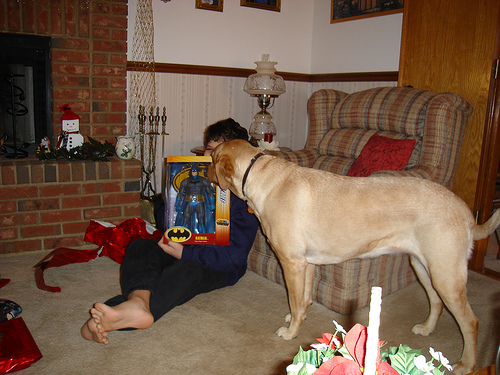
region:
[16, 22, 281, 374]
A boy opening presents.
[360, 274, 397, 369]
White handle to flower container.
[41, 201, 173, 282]
Red wrapping paper.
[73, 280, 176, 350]
There are no socks on feet.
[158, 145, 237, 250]
A box with Batman.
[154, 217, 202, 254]
A black and yellow batman logo.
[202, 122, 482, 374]
A large beige dog.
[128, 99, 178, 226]
Set of fireplace tools.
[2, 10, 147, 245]
A red brick fireplace.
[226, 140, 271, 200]
Collar on dog's neck.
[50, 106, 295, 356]
The boy sits on the floor.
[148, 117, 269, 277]
The boy holds a toy.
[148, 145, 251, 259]
The toy is a Batman doll.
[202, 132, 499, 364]
The dog is smelling the toy.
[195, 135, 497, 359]
The dog is tan.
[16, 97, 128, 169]
Christmas ornaments are on the fireplace.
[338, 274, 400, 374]
A candle is visible.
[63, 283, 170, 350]
The boy is barefoot.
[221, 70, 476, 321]
A chair is behind the boy.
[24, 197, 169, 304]
Wrapping paper is on the floor.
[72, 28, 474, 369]
child and dog in corner of living room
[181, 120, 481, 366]
tan dog looking at toy in box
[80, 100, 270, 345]
child sitting on floor showing unwrapped gift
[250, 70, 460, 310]
hefty plaid chair in rust and browns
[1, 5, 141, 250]
bricks surrounding unlit fireplace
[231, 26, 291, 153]
old-fashioned lamp with dome shapes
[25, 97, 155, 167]
vase, branch and snowman decoration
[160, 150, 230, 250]
muscular superhero standing with cape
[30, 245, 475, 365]
tan carpeting covering floor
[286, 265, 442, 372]
seasonal plastic floral basket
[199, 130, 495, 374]
Dog is tan with collar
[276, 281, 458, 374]
White basket with flowers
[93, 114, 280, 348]
Boy holding batman doll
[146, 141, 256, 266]
Batman doll in a box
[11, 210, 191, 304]
Red wrapping paper on floor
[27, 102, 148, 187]
Snowman on fireplace with red hat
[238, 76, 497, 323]
Brown striped chair with red pillow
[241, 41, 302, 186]
old lamp next to chair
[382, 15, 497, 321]
Wooden door behind chair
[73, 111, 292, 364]
Boy not wearing shoes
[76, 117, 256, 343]
A boy holding a batman action figure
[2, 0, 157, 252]
The fireplace is made of brick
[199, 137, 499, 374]
The tan dog is sniffing the box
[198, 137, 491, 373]
The black collar on the tan dog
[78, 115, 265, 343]
The boy is sitting on the floor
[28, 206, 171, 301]
The gift wrapping is on the floor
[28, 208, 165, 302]
The gift wrapping is red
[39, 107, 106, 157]
The snowman at the fireplace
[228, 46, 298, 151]
The lamp behind the boy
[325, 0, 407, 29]
the picture on the wall